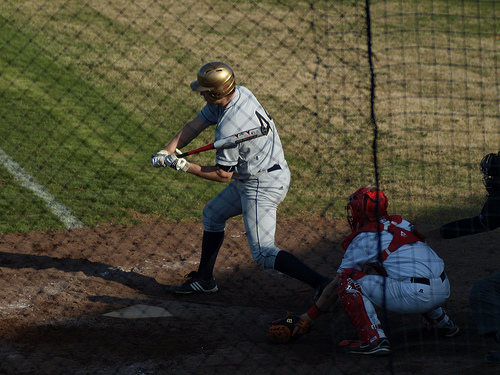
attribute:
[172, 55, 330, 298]
batter — swinging, ready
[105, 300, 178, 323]
plate — shadowed, white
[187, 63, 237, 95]
helmet — gold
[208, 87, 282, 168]
shirt — grey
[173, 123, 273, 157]
bat — red, swinging, aluminum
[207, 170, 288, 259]
pants — grey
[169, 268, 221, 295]
shoe — dark, striped, black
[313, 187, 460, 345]
catcher — crouching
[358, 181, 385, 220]
helmet — red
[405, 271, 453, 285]
belt — black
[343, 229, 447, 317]
outfit — white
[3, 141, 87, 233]
line — white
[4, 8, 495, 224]
grass — green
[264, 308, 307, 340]
mitt — held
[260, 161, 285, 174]
belt — black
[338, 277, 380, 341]
pads — red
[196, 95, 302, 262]
uniform — grey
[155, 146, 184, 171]
gloves — white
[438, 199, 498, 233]
jacket — black